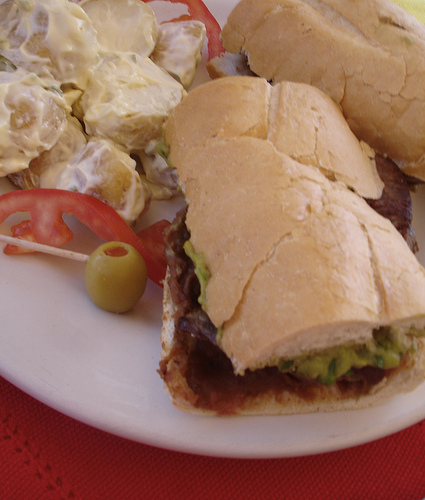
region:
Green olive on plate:
[85, 244, 153, 311]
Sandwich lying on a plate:
[169, 80, 423, 407]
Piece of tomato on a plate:
[1, 189, 177, 278]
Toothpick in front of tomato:
[3, 232, 89, 264]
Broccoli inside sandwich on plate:
[303, 330, 402, 379]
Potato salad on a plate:
[3, 0, 213, 213]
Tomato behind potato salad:
[156, 3, 237, 55]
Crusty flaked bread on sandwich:
[194, 212, 279, 324]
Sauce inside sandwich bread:
[199, 365, 268, 404]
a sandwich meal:
[0, 5, 423, 496]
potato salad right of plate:
[2, 0, 168, 193]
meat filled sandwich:
[168, 76, 381, 403]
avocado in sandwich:
[281, 346, 390, 381]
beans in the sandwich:
[171, 251, 192, 300]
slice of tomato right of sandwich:
[0, 188, 130, 236]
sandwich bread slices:
[219, 112, 369, 339]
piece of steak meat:
[381, 155, 412, 219]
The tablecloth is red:
[0, 388, 419, 492]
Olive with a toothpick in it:
[0, 213, 151, 325]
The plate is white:
[14, 38, 405, 469]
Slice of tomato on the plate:
[0, 184, 173, 290]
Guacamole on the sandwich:
[281, 344, 404, 374]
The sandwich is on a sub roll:
[162, 6, 408, 424]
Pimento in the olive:
[105, 247, 130, 261]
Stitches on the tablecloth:
[0, 402, 76, 496]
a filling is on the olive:
[103, 244, 126, 261]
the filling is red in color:
[104, 240, 129, 261]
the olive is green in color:
[82, 241, 147, 315]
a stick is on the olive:
[2, 231, 88, 277]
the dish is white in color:
[0, 183, 424, 496]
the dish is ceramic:
[0, 180, 417, 498]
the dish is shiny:
[1, 223, 420, 498]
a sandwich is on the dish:
[133, 83, 424, 427]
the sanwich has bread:
[149, 63, 424, 422]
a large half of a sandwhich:
[166, 82, 406, 431]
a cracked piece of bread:
[227, 229, 286, 312]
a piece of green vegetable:
[302, 339, 363, 373]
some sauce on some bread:
[168, 345, 243, 416]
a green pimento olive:
[91, 238, 138, 302]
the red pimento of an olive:
[103, 238, 128, 261]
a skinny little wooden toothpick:
[10, 214, 73, 277]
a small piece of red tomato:
[37, 179, 128, 254]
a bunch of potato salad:
[21, 36, 144, 172]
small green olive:
[78, 240, 155, 314]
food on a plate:
[347, 47, 423, 104]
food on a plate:
[186, 76, 328, 162]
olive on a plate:
[81, 240, 136, 304]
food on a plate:
[4, 68, 52, 120]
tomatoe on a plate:
[13, 189, 88, 227]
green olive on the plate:
[61, 229, 147, 306]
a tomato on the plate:
[10, 151, 160, 320]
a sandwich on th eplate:
[130, 93, 421, 480]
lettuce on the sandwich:
[295, 326, 390, 406]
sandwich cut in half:
[139, 44, 423, 393]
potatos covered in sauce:
[69, 45, 136, 128]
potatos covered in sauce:
[7, 73, 76, 162]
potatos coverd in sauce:
[53, 13, 131, 68]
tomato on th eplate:
[160, 17, 231, 56]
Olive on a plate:
[65, 239, 154, 347]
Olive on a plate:
[65, 233, 156, 338]